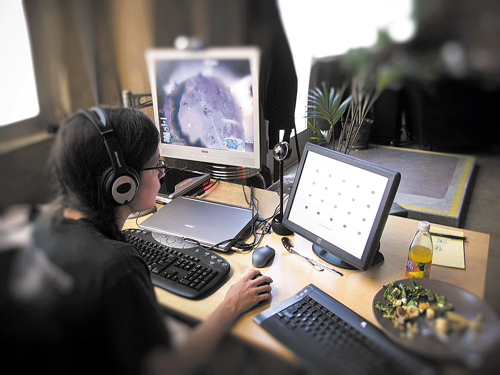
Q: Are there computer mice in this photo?
A: Yes, there is a computer mouse.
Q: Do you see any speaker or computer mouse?
A: Yes, there is a computer mouse.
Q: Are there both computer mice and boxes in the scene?
A: No, there is a computer mouse but no boxes.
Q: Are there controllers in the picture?
A: No, there are no controllers.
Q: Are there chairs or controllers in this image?
A: No, there are no controllers or chairs.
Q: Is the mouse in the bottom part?
A: Yes, the mouse is in the bottom of the image.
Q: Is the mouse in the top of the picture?
A: No, the mouse is in the bottom of the image.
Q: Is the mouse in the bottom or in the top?
A: The mouse is in the bottom of the image.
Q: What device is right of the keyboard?
A: The device is a computer mouse.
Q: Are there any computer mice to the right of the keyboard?
A: Yes, there is a computer mouse to the right of the keyboard.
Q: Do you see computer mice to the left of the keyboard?
A: No, the computer mouse is to the right of the keyboard.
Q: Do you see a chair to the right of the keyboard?
A: No, there is a computer mouse to the right of the keyboard.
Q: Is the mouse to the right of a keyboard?
A: Yes, the mouse is to the right of a keyboard.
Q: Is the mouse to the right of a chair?
A: No, the mouse is to the right of a keyboard.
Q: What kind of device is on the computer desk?
A: The device is a computer mouse.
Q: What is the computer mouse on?
A: The computer mouse is on the computer desk.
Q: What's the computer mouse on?
A: The computer mouse is on the computer desk.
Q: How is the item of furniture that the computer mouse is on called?
A: The piece of furniture is a computer desk.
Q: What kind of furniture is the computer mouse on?
A: The computer mouse is on the computer desk.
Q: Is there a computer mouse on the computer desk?
A: Yes, there is a computer mouse on the computer desk.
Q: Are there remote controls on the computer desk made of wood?
A: No, there is a computer mouse on the computer desk.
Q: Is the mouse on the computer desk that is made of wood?
A: Yes, the mouse is on the computer desk.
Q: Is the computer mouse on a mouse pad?
A: No, the computer mouse is on the computer desk.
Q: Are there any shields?
A: No, there are no shields.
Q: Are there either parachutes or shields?
A: No, there are no shields or parachutes.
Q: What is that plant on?
A: The plant is on the computer desk.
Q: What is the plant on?
A: The plant is on the computer desk.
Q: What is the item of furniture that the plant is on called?
A: The piece of furniture is a computer desk.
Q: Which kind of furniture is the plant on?
A: The plant is on the computer desk.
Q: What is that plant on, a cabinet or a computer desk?
A: The plant is on a computer desk.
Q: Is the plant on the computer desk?
A: Yes, the plant is on the computer desk.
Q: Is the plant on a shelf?
A: No, the plant is on the computer desk.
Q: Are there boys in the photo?
A: No, there are no boys.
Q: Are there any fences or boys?
A: No, there are no boys or fences.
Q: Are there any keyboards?
A: Yes, there is a keyboard.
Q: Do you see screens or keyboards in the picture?
A: Yes, there is a keyboard.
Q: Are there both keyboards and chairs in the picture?
A: No, there is a keyboard but no chairs.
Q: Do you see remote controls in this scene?
A: No, there are no remote controls.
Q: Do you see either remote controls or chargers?
A: No, there are no remote controls or chargers.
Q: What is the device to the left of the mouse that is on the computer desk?
A: The device is a keyboard.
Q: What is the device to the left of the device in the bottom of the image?
A: The device is a keyboard.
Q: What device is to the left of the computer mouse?
A: The device is a keyboard.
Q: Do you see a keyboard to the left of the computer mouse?
A: Yes, there is a keyboard to the left of the computer mouse.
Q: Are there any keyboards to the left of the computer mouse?
A: Yes, there is a keyboard to the left of the computer mouse.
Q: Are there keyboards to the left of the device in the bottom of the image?
A: Yes, there is a keyboard to the left of the computer mouse.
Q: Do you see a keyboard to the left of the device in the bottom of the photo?
A: Yes, there is a keyboard to the left of the computer mouse.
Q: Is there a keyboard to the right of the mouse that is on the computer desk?
A: No, the keyboard is to the left of the computer mouse.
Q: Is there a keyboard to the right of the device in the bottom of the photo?
A: No, the keyboard is to the left of the computer mouse.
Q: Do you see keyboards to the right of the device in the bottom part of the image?
A: No, the keyboard is to the left of the computer mouse.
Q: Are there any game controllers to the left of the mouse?
A: No, there is a keyboard to the left of the mouse.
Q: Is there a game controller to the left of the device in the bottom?
A: No, there is a keyboard to the left of the mouse.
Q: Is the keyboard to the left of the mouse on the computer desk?
A: Yes, the keyboard is to the left of the mouse.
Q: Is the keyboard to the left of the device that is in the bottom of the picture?
A: Yes, the keyboard is to the left of the mouse.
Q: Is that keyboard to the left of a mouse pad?
A: No, the keyboard is to the left of the mouse.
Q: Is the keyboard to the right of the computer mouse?
A: No, the keyboard is to the left of the computer mouse.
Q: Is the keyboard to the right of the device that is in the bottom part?
A: No, the keyboard is to the left of the computer mouse.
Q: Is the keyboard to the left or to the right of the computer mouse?
A: The keyboard is to the left of the computer mouse.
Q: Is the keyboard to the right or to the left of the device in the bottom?
A: The keyboard is to the left of the computer mouse.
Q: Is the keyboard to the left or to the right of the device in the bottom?
A: The keyboard is to the left of the computer mouse.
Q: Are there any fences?
A: No, there are no fences.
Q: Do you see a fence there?
A: No, there are no fences.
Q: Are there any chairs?
A: No, there are no chairs.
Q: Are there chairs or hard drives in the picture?
A: No, there are no chairs or hard drives.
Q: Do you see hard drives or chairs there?
A: No, there are no chairs or hard drives.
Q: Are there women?
A: Yes, there is a woman.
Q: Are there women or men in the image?
A: Yes, there is a woman.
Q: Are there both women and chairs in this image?
A: No, there is a woman but no chairs.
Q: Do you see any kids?
A: No, there are no kids.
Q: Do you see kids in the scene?
A: No, there are no kids.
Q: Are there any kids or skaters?
A: No, there are no kids or skaters.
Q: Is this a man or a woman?
A: This is a woman.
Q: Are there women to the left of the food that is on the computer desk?
A: Yes, there is a woman to the left of the food.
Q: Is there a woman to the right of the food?
A: No, the woman is to the left of the food.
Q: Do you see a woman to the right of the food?
A: No, the woman is to the left of the food.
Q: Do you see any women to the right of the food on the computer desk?
A: No, the woman is to the left of the food.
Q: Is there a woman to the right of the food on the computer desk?
A: No, the woman is to the left of the food.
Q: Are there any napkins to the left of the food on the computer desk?
A: No, there is a woman to the left of the food.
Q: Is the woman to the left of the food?
A: Yes, the woman is to the left of the food.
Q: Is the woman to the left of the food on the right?
A: Yes, the woman is to the left of the food.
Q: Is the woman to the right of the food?
A: No, the woman is to the left of the food.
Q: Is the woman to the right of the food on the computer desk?
A: No, the woman is to the left of the food.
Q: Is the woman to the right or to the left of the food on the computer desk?
A: The woman is to the left of the food.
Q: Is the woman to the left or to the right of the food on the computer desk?
A: The woman is to the left of the food.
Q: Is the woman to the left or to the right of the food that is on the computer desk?
A: The woman is to the left of the food.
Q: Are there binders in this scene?
A: No, there are no binders.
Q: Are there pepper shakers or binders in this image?
A: No, there are no binders or pepper shakers.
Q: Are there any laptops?
A: Yes, there is a laptop.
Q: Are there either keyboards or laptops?
A: Yes, there is a laptop.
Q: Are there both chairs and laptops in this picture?
A: No, there is a laptop but no chairs.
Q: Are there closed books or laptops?
A: Yes, there is a closed laptop.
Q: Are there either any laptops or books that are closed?
A: Yes, the laptop is closed.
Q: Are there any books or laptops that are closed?
A: Yes, the laptop is closed.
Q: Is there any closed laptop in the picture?
A: Yes, there is a closed laptop.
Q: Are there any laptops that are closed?
A: Yes, there is a closed laptop.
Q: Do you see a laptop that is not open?
A: Yes, there is an closed laptop.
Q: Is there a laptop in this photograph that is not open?
A: Yes, there is an closed laptop.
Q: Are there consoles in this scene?
A: No, there are no consoles.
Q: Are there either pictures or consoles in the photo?
A: No, there are no consoles or pictures.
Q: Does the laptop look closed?
A: Yes, the laptop is closed.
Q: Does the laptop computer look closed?
A: Yes, the laptop computer is closed.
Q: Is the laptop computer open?
A: No, the laptop computer is closed.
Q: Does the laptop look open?
A: No, the laptop is closed.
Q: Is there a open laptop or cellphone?
A: No, there is a laptop but it is closed.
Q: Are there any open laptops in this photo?
A: No, there is a laptop but it is closed.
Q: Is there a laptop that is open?
A: No, there is a laptop but it is closed.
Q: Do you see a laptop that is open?
A: No, there is a laptop but it is closed.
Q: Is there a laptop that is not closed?
A: No, there is a laptop but it is closed.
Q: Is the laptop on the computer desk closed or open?
A: The laptop computer is closed.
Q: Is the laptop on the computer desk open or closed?
A: The laptop computer is closed.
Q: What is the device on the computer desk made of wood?
A: The device is a laptop.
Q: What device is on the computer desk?
A: The device is a laptop.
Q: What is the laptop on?
A: The laptop is on the computer desk.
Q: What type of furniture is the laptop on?
A: The laptop is on the computer desk.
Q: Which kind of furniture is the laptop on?
A: The laptop is on the computer desk.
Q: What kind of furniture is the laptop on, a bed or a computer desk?
A: The laptop is on a computer desk.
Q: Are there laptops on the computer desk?
A: Yes, there is a laptop on the computer desk.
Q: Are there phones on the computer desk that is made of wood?
A: No, there is a laptop on the computer desk.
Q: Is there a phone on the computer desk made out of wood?
A: No, there is a laptop on the computer desk.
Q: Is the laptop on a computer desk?
A: Yes, the laptop is on a computer desk.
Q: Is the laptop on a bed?
A: No, the laptop is on a computer desk.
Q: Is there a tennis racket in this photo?
A: No, there are no rackets.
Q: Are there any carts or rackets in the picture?
A: No, there are no rackets or carts.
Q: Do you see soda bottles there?
A: No, there are no soda bottles.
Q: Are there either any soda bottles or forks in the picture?
A: No, there are no soda bottles or forks.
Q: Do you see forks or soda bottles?
A: No, there are no soda bottles or forks.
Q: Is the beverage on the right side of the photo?
A: Yes, the beverage is on the right of the image.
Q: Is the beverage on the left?
A: No, the beverage is on the right of the image.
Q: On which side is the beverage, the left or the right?
A: The beverage is on the right of the image.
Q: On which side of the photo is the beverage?
A: The beverage is on the right of the image.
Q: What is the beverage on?
A: The beverage is on the computer desk.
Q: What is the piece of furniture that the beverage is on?
A: The piece of furniture is a computer desk.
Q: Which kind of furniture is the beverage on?
A: The beverage is on the computer desk.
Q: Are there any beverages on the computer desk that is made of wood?
A: Yes, there is a beverage on the computer desk.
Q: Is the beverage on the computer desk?
A: Yes, the beverage is on the computer desk.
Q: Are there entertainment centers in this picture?
A: No, there are no entertainment centers.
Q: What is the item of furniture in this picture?
A: The piece of furniture is a computer desk.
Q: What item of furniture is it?
A: The piece of furniture is a computer desk.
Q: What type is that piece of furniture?
A: This is a computer desk.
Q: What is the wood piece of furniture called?
A: The piece of furniture is a computer desk.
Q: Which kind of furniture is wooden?
A: The furniture is a computer desk.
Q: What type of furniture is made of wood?
A: The furniture is a computer desk.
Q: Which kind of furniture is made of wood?
A: The furniture is a computer desk.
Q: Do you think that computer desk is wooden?
A: Yes, the computer desk is wooden.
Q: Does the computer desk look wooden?
A: Yes, the computer desk is wooden.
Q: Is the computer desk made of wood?
A: Yes, the computer desk is made of wood.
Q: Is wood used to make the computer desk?
A: Yes, the computer desk is made of wood.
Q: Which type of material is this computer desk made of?
A: The computer desk is made of wood.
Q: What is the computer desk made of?
A: The computer desk is made of wood.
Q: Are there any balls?
A: No, there are no balls.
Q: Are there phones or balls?
A: No, there are no balls or phones.